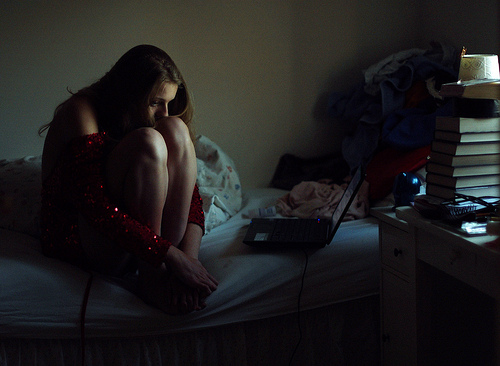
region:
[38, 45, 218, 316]
A woman sitting on a bed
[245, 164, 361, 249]
A laptop sitting on a bed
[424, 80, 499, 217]
A stack of books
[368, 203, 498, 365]
A white wooden desk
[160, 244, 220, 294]
A woman's right hand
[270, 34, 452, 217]
A messy pile of cloths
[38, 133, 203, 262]
A girl's red sequined blouse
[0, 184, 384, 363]
A girl's bed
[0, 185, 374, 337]
A white bed sheet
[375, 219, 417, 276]
Drawer of a wooden desk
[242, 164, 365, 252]
Black laptop computer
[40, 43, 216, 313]
Young woman in red dress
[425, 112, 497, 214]
Large pile of hardcover books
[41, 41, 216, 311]
Woman sitting on bed with hands around knees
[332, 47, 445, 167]
Pile of clothing and towels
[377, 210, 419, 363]
White desk drawer and cabinet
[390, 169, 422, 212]
Dark blue circular desk fan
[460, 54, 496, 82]
Top half of a cream colored lamp shade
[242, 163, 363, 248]
Dark colored laptop sitting on bed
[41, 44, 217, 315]
Long haired brunette in red sequined dress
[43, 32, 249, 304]
The girl is wearing a red sparkly shirt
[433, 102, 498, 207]
Stack of books on the counter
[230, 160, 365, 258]
The laptop is black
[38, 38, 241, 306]
The girl is sitting on the bed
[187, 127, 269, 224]
The blanket is white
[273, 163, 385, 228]
The clothes are pink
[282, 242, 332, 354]
Black wire from the laptop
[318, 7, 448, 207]
A pile of clothes at the end of the bed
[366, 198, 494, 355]
The desk is white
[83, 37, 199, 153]
The girl has long brown hair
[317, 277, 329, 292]
edge of a bed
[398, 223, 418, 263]
part of a table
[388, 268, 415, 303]
edge of a table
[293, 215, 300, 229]
part of a laptop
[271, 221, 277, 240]
edge of a laptop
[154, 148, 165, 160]
part of a knee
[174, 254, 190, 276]
hand of a girl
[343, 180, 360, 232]
edge of a laptop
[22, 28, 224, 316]
a woman wearing a red sparkly dress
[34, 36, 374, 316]
a woman in front of her laptop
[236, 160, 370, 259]
a laptop on the bed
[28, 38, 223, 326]
a woman on the bed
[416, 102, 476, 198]
pile of books on top of the table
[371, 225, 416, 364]
drawers of the desk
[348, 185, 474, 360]
a desk next to the bed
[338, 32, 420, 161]
pile of clothes on the bed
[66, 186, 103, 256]
a sparkly red dress the woman is wearing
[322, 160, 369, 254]
the monitor of the laptop